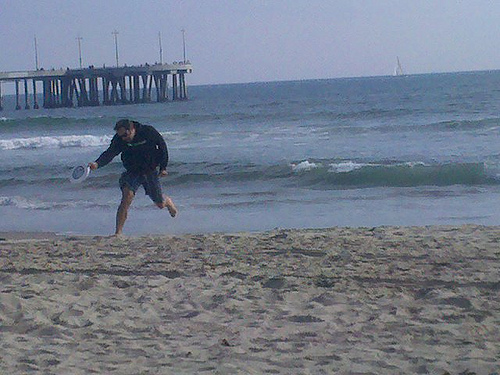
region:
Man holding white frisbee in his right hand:
[62, 110, 209, 234]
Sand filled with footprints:
[49, 248, 480, 368]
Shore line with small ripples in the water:
[221, 187, 446, 254]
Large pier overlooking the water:
[3, 9, 208, 112]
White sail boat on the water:
[380, 55, 437, 97]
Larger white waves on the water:
[6, 113, 93, 154]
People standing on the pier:
[125, 58, 199, 74]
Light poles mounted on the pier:
[30, 26, 202, 62]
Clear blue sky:
[222, 12, 362, 69]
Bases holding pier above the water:
[13, 79, 198, 106]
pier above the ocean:
[11, 58, 188, 106]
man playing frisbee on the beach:
[63, 110, 183, 245]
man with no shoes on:
[70, 109, 184, 243]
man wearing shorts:
[85, 114, 192, 244]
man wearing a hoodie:
[92, 108, 184, 238]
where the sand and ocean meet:
[191, 199, 494, 256]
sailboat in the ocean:
[385, 48, 414, 88]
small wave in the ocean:
[285, 154, 485, 193]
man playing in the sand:
[92, 114, 188, 247]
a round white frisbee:
[57, 158, 94, 186]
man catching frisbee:
[68, 118, 190, 238]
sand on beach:
[5, 221, 498, 368]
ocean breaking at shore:
[13, 82, 499, 186]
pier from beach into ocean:
[1, 50, 193, 107]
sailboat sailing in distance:
[390, 53, 410, 78]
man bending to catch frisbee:
[66, 113, 181, 236]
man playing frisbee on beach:
[68, 116, 178, 242]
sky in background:
[3, 5, 498, 61]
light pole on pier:
[108, 25, 125, 65]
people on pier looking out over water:
[121, 60, 191, 67]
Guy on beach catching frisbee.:
[84, 112, 179, 237]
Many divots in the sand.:
[225, 242, 320, 336]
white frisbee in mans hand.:
[70, 163, 88, 181]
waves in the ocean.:
[289, 156, 445, 190]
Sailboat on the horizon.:
[394, 56, 405, 78]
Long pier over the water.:
[0, 58, 207, 105]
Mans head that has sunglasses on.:
[115, 119, 137, 147]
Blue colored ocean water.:
[405, 78, 444, 107]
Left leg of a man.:
[145, 172, 179, 217]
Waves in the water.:
[0, 133, 92, 149]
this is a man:
[76, 119, 171, 237]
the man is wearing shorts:
[118, 171, 160, 187]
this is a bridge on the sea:
[0, 55, 187, 107]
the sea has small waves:
[224, 141, 469, 196]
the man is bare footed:
[107, 199, 174, 230]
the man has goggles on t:
[118, 132, 125, 137]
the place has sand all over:
[21, 241, 496, 373]